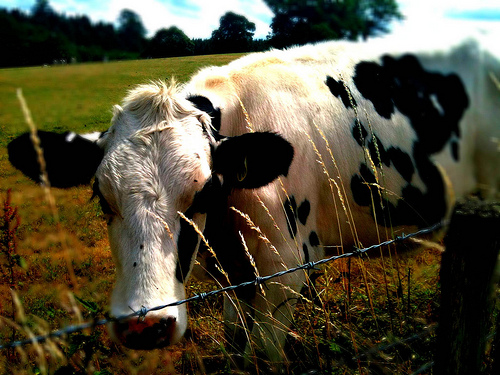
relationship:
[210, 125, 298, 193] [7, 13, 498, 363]
ear on cow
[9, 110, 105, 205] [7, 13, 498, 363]
ear on cow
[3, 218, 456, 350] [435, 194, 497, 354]
barbed wire on post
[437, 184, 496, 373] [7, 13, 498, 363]
fence post in front of cow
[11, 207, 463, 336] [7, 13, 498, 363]
barbed wire in front of cow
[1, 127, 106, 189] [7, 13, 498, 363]
ear on cow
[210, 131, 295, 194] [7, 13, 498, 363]
ear on cow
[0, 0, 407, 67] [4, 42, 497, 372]
trees on field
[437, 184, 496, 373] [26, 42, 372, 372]
fence post by cow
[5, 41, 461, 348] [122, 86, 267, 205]
field behind cow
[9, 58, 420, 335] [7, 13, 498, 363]
pasture behind cow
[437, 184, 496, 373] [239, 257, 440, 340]
fence post holding fence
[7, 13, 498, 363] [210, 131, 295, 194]
cow has ear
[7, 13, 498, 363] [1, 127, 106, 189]
cow has ear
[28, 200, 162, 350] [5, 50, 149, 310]
plant growing in pasture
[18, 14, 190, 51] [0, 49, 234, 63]
trees on horizon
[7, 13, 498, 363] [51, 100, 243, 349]
cow has head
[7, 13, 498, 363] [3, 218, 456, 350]
cow behind barbed wire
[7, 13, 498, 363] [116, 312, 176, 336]
cow has nose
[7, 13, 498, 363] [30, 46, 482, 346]
cow standing in field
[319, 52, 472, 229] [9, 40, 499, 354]
black spots on cow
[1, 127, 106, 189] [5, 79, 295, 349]
ear on head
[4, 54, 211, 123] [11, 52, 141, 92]
grass on hill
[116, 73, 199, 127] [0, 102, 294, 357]
hair on head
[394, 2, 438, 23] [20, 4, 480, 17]
clouds in sky